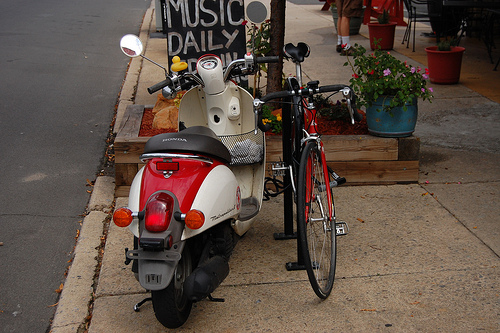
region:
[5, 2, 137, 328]
flat gray pavement of road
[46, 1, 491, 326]
gray panels of sidewalk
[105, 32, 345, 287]
scooter parked next to bicycle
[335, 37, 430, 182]
pot of flowers on wooden rails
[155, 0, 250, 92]
large lettering on black sign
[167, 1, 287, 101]
thin plant between trunk and sign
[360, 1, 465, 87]
pair of planters on sidewalk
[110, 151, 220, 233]
three red lights at end of red panel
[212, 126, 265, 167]
white fabric in netted pouch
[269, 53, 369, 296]
red bicycle parked on the sidewalk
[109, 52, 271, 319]
red and white moped on sidewalk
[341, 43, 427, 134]
blue planter with flowers planted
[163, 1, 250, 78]
black sign with white lettering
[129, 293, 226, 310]
kickstand on the moped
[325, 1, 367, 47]
person standing on sidewalk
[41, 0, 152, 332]
curb of the sidewalk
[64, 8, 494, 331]
sidewalk bicycle and moped are on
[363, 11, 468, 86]
two red planters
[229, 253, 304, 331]
A brown rough ground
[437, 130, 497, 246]
A brown rough ground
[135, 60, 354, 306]
A small motor bike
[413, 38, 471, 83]
A red flower pot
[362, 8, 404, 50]
A red flower pot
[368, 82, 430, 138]
A blue flower pot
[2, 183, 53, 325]
A grey tarmac road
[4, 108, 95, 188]
A grey tarmac road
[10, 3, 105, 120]
A grey tarmac road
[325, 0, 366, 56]
legs of person next to plant pot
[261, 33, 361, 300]
bicycle parked next to moped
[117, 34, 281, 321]
moped parked on the sidewalk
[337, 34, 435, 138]
plant pot next to bicycle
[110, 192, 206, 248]
back lights of moped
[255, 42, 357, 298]
bicycle leaning on railing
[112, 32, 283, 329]
red and white moped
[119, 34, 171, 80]
left rear-view-mirror on moped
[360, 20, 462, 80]
two orange plant pots on the sidewalk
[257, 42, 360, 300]
red and black bike on the sidewalk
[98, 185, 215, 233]
lights on back of scooter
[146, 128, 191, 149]
small writing on scooter seat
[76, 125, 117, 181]
trash laying beside sidewalk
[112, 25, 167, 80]
mirror on front of scooter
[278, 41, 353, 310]
bicycle parked on sidewalk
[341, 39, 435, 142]
small plant in blue pot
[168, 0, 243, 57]
white writing on black sign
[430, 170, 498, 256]
cracks in sidewalk concrete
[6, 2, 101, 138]
black pavement on road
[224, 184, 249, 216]
design on side of scooter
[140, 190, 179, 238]
red light on back of the scooter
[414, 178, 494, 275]
a crack in the sidewalk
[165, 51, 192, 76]
a yellow rubber duck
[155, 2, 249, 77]
a black sign with white letters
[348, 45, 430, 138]
a blue pot with pink flowers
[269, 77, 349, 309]
a red bicycle on the sidewalk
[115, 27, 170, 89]
a mirror on the scooter